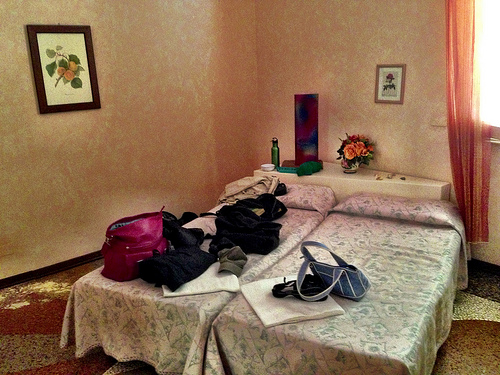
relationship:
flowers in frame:
[42, 45, 89, 94] [80, 29, 100, 104]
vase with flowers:
[342, 140, 362, 171] [340, 139, 362, 152]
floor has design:
[10, 277, 51, 368] [470, 276, 499, 374]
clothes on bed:
[179, 213, 240, 288] [296, 192, 343, 243]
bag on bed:
[93, 206, 141, 289] [296, 192, 343, 243]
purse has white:
[290, 230, 373, 300] [345, 270, 361, 301]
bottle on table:
[264, 135, 289, 167] [333, 167, 435, 185]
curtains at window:
[451, 5, 477, 187] [477, 8, 499, 120]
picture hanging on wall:
[372, 56, 411, 107] [331, 11, 383, 51]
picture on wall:
[23, 19, 122, 126] [11, 127, 110, 179]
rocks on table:
[379, 173, 408, 183] [333, 167, 435, 185]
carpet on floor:
[456, 276, 485, 373] [10, 277, 51, 368]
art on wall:
[372, 56, 411, 107] [331, 11, 383, 51]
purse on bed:
[290, 230, 373, 300] [296, 192, 343, 243]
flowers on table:
[340, 139, 362, 152] [333, 167, 435, 185]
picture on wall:
[372, 56, 411, 107] [331, 11, 383, 51]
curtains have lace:
[451, 5, 477, 187] [464, 235, 489, 251]